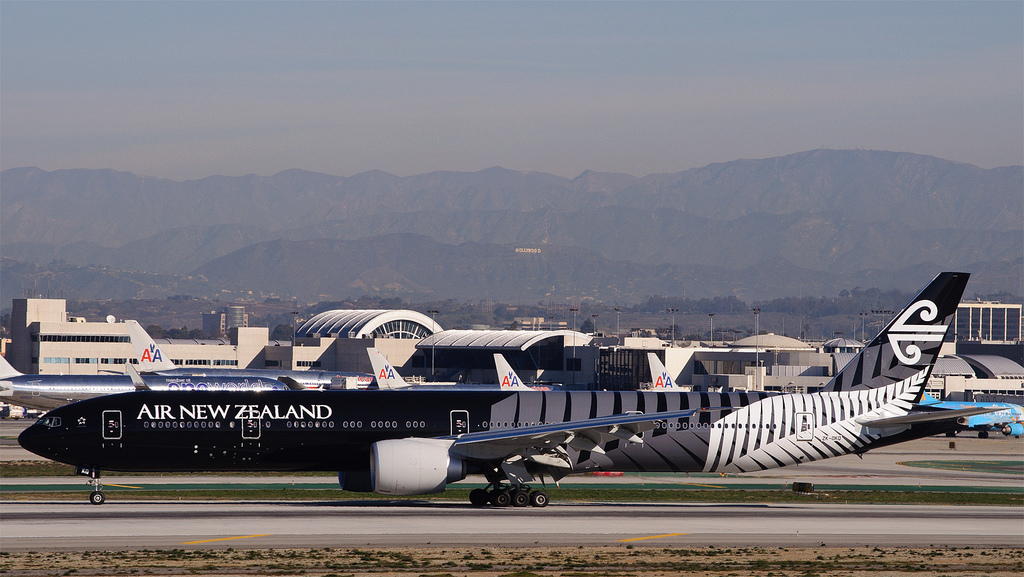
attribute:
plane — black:
[10, 262, 1020, 518]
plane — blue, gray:
[168, 325, 328, 490]